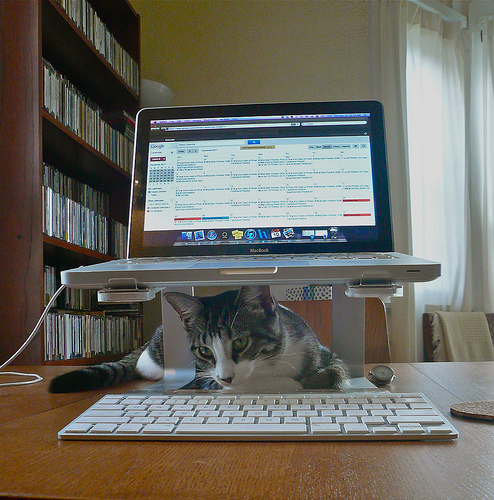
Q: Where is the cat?
A: Under the laptop stand.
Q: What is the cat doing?
A: Hiding.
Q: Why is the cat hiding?
A: He likes to hide.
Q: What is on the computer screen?
A: An appointment calendar.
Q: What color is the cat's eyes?
A: Yellow and Green.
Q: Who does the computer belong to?
A: The owner of the house.